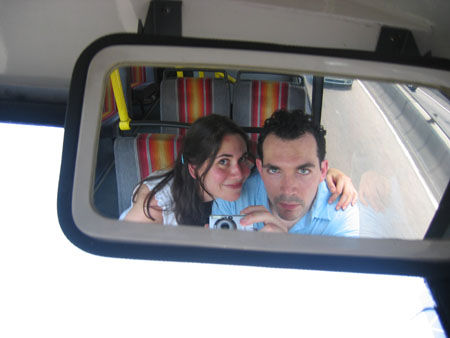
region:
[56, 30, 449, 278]
Black border around a mirror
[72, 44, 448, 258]
Gray border around a mirror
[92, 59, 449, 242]
Reflective portion of a mirror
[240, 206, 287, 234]
left hand of a man taking a picture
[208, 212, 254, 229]
silver camera being used to take a picture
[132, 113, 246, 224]
long brown hair of the woman in the photo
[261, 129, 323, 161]
high forehead of the man taking the photo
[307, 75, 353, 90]
vehicle on the road to the right of the couple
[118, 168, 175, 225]
white sleeveless top on the woman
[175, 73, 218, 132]
multi-colored stripes on a seat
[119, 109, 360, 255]
There is a man and a woman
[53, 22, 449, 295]
there is a mirror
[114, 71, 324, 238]
The seats are grey, red and yellow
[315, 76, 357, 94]
There is a front of a car in the distance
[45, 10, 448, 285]
The mirror has a black border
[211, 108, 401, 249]
The man has blue eyes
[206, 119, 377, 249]
The man wears a blue shirt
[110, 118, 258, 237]
the woman wears a white shirt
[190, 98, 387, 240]
the man holds the camera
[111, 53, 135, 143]
There is a yellow pole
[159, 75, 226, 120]
a chair on a vehicle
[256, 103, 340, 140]
black hair on a man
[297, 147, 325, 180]
a mans left eye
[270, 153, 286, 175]
a mans right eye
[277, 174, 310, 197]
a mans nose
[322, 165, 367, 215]
a womans left hand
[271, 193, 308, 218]
a mans mouth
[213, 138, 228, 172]
a womans right eye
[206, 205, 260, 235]
a camera with fingers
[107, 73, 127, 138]
a long yellow bar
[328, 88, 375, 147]
road outside bus window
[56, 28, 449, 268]
picture taken with bus mirror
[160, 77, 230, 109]
bus seats are grey with yellow, red, orange and purple stripes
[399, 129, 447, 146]
concrete road divider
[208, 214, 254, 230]
camera that took this photo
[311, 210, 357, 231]
light sky blue shirt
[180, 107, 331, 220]
heads are close together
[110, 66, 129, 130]
yellow seat rail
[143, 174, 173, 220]
sleeveless white blouse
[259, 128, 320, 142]
window's peak receding hairline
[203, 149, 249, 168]
A pair of womens eyes.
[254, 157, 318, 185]
A pair of mans eyes.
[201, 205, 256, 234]
Black and silver camera.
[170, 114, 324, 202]
Man and a woman.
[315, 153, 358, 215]
Hand on a shoulder.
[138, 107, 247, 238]
Woman with long brown hair.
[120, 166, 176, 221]
Short sleeved shirt.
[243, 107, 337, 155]
Short brown curly hair.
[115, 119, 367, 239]
Two people taking a picture.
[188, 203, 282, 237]
A hand holding a camera.